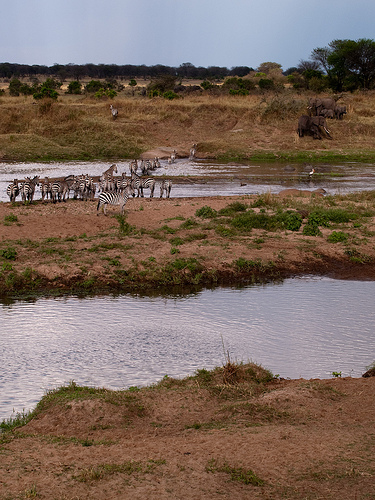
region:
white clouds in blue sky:
[44, 416, 126, 457]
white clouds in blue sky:
[142, 411, 235, 460]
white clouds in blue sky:
[211, 440, 283, 493]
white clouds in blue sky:
[283, 405, 354, 458]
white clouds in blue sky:
[34, 223, 82, 250]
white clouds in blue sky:
[173, 110, 223, 138]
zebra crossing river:
[104, 162, 145, 200]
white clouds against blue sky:
[11, 10, 67, 62]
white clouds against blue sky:
[87, 13, 128, 50]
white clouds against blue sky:
[164, 5, 249, 47]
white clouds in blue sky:
[4, 4, 77, 40]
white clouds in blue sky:
[14, 26, 55, 58]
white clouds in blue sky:
[77, 15, 133, 65]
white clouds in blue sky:
[137, 12, 156, 59]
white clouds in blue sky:
[174, 19, 195, 58]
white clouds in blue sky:
[220, 17, 252, 52]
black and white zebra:
[85, 180, 130, 215]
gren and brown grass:
[152, 403, 190, 445]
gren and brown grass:
[210, 401, 290, 463]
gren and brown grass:
[58, 423, 101, 459]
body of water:
[7, 293, 343, 405]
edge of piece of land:
[43, 372, 360, 458]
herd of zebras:
[15, 156, 248, 247]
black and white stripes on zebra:
[88, 183, 120, 213]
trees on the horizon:
[4, 56, 275, 89]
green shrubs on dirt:
[176, 206, 371, 259]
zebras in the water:
[154, 152, 219, 191]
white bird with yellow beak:
[303, 164, 327, 184]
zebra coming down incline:
[98, 98, 134, 127]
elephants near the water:
[283, 83, 356, 186]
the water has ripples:
[275, 303, 317, 334]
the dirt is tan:
[289, 432, 313, 457]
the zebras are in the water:
[138, 157, 170, 174]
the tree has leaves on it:
[328, 39, 351, 60]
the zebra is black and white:
[102, 183, 142, 202]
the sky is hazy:
[177, 19, 222, 43]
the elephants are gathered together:
[304, 94, 350, 120]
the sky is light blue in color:
[210, 20, 244, 39]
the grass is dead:
[154, 97, 184, 116]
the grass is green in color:
[241, 205, 286, 230]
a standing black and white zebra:
[158, 174, 171, 199]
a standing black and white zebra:
[95, 185, 137, 212]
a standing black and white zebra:
[5, 178, 18, 203]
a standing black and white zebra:
[20, 174, 39, 205]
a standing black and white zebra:
[39, 174, 50, 200]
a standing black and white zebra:
[48, 176, 71, 201]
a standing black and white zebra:
[139, 155, 149, 175]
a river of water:
[0, 270, 372, 426]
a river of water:
[3, 157, 373, 199]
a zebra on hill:
[104, 103, 119, 119]